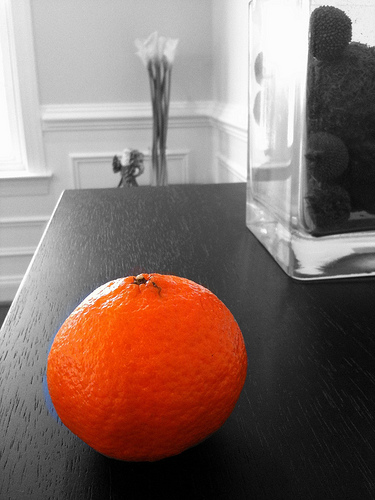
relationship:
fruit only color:
[40, 263, 249, 464] [49, 272, 247, 462]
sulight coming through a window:
[3, 101, 20, 172] [0, 1, 53, 198]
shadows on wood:
[58, 282, 372, 496] [2, 184, 374, 499]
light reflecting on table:
[19, 219, 86, 302] [2, 184, 374, 499]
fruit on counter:
[40, 263, 249, 464] [2, 2, 372, 497]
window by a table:
[0, 1, 53, 198] [2, 184, 374, 499]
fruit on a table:
[40, 263, 249, 464] [2, 184, 374, 499]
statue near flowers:
[112, 148, 147, 186] [133, 29, 178, 185]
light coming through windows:
[19, 219, 86, 302] [0, 1, 53, 198]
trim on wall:
[40, 103, 218, 132] [18, 2, 231, 188]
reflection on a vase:
[247, 2, 307, 277] [245, 2, 373, 280]